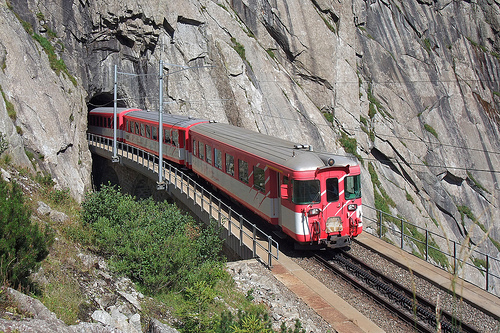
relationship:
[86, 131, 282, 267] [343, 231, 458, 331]
railing on side of tracks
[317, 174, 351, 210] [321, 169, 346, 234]
stripes on red door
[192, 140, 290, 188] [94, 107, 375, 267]
windows on train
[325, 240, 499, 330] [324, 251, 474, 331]
gravel on tracks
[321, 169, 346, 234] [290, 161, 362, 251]
red door on front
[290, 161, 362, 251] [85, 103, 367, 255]
front of train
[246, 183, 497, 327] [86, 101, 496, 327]
tracks of railroad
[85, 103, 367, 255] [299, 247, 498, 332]
train on tracks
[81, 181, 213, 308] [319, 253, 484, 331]
bushes beside tracks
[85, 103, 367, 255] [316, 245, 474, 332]
train on tracks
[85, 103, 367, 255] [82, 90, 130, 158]
train in train tunnel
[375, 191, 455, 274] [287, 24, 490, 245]
plants on cliff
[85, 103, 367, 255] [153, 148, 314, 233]
train with stripe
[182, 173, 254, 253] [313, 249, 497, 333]
railing besides tracks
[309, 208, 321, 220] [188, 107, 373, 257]
light on train